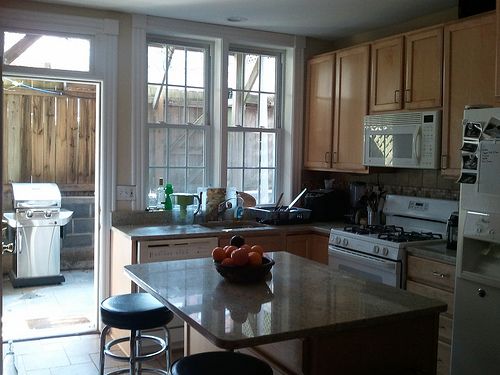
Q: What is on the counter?
A: A bowl of fruit.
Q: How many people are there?
A: None.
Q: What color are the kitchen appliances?
A: White.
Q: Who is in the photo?
A: Nobody.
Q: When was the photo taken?
A: Daytime.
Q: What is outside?
A: A grill.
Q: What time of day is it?
A: Morning.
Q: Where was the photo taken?
A: In a kitchen.